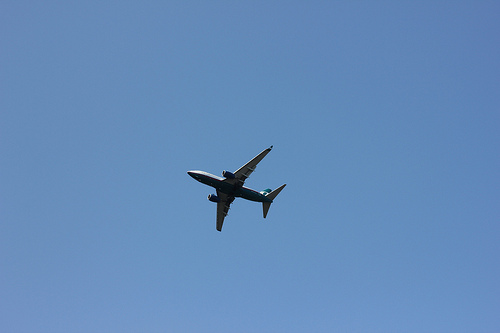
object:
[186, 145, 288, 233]
airplane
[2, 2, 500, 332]
sky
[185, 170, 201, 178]
tip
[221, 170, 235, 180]
engine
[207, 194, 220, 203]
engine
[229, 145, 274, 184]
wing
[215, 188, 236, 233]
wing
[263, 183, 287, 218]
tail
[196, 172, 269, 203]
body